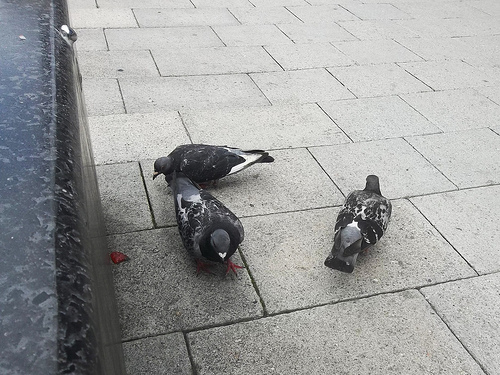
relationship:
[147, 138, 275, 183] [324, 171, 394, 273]
pigeon scrounging pigeon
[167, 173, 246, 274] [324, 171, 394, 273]
pigeon scrounging pigeon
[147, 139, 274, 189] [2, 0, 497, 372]
dove on ground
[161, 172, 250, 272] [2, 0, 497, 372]
dove on ground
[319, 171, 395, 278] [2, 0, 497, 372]
dove on ground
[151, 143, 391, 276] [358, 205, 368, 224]
birds have stripes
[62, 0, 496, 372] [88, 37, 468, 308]
floor has slabs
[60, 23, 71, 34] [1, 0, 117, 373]
droppings on marble wall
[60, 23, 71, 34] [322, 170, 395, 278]
droppings of bird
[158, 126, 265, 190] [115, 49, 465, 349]
pigeon on sidewalk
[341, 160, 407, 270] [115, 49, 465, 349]
pigeon on sidewalk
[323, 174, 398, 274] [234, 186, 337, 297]
pigeons looks food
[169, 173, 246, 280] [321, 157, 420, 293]
pigeon has feathers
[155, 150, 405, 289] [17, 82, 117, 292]
pigeons near marble wall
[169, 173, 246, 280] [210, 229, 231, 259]
pigeon has head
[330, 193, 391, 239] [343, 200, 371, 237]
wing has white feathers